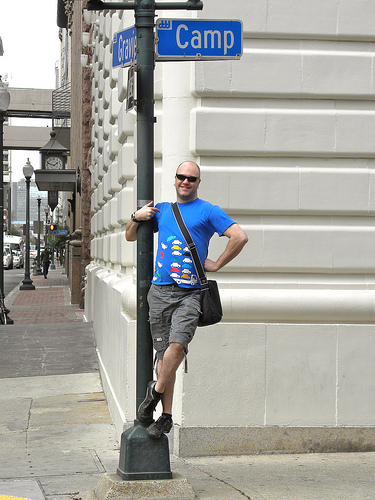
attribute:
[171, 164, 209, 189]
sunglasses — black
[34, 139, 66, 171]
clock — on the post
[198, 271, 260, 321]
bag — black, leather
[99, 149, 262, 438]
man — standing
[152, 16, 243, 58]
sign — on the post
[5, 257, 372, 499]
sidewalk — on the post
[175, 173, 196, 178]
sunglasses — dark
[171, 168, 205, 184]
sunglasses — on the post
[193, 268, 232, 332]
bag — on the table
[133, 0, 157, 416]
pole — metal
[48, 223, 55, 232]
light — orange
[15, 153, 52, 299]
light — on the post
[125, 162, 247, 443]
man — on the post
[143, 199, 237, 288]
tshirt — blue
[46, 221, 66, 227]
light — red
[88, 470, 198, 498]
podium — concrete